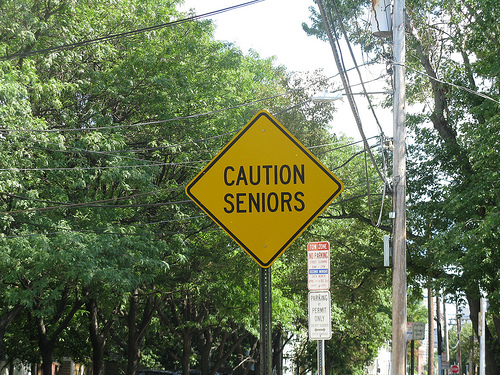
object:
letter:
[236, 166, 248, 186]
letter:
[249, 165, 260, 184]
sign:
[185, 111, 342, 267]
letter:
[262, 165, 272, 185]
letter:
[224, 166, 235, 186]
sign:
[308, 291, 332, 341]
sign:
[451, 365, 459, 372]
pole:
[392, 0, 406, 375]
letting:
[223, 164, 304, 213]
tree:
[0, 0, 186, 375]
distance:
[0, 191, 500, 349]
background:
[0, 0, 500, 192]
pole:
[261, 267, 272, 375]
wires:
[0, 0, 254, 62]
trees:
[306, 0, 495, 375]